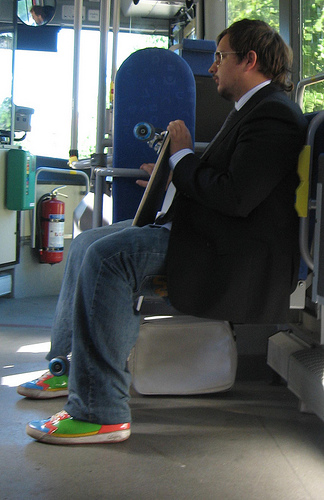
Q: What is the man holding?
A: A skateboard.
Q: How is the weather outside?
A: Very sunny.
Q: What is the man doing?
A: He is sitting.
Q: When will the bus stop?
A: At the next stop.